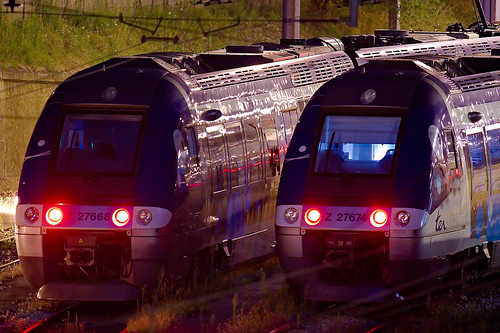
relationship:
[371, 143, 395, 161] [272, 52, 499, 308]
lights inside train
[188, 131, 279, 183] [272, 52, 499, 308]
reflection on train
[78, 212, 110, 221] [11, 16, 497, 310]
numbers on train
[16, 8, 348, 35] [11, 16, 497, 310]
wire above train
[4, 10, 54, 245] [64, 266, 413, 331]
grass beside track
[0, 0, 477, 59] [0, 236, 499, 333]
grass along railroad track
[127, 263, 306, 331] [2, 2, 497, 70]
grass on hillside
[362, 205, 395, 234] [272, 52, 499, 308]
light on train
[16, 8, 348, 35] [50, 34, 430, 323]
wire above train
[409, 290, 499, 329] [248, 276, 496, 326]
gravel around tracks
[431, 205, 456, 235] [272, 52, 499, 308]
ter on train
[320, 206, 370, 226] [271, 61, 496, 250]
number on train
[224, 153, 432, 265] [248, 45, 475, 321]
lights on train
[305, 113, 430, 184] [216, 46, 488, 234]
windows on train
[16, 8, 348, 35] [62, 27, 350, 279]
wire for train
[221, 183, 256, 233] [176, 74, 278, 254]
coloring on side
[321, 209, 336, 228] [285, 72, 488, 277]
letter on train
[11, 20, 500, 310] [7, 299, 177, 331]
train on tracks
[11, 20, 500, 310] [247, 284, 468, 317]
train on tracks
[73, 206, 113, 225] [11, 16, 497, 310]
numbers on train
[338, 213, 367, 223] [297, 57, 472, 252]
number on train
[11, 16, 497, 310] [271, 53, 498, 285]
train side by side train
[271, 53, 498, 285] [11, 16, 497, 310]
train side by side train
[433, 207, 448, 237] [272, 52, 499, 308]
lettering on side of train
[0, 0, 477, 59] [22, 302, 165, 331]
grass on tracks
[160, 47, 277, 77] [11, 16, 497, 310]
top on train